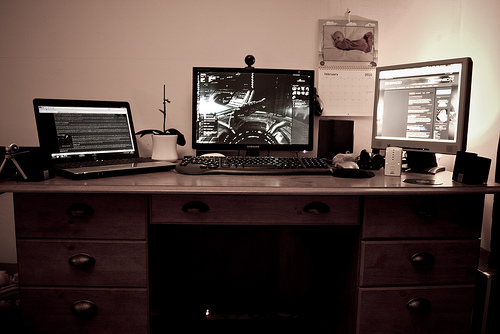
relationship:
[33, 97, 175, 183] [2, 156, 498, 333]
laptop on desk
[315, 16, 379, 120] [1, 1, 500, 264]
calendar hanging on wall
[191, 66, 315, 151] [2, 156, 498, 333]
monitor on desk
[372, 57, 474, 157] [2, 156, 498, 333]
monitor on desk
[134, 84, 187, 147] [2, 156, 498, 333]
plant on desk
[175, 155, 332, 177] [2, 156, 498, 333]
keyboard on desk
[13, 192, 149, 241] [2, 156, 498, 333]
drawer in desk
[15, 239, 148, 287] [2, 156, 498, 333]
drawer in desk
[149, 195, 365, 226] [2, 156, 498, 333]
drawer in desk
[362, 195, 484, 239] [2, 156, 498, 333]
drawer in desk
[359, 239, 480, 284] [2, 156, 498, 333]
drawer in desk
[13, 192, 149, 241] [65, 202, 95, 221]
drawer has handle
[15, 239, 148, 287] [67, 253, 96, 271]
drawer has handle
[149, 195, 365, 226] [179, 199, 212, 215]
drawer has handle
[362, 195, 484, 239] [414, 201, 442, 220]
drawer has handle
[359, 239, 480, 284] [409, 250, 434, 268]
drawer has handle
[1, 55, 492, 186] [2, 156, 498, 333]
objects are on desk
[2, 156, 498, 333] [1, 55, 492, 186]
desk under objects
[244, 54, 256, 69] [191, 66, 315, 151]
webcam on monitor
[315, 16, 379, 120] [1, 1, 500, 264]
calendar on wall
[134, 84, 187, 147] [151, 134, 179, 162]
plant in pot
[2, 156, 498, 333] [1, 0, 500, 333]
desk in office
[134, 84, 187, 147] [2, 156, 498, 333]
plant sitting on desk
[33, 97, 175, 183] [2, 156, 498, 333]
laptop sitting on desk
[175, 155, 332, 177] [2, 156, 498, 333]
keyboard sitting on desk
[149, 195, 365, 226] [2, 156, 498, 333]
drawer on desk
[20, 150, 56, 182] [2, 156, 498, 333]
speaker on desk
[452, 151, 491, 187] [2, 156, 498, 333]
speaker on desk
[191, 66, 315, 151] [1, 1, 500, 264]
monitor against wall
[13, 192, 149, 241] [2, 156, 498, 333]
drawer in front of desk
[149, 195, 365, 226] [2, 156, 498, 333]
drawer in front of desk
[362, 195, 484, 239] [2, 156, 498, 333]
drawer in front of desk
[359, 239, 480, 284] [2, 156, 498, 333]
drawer in front of desk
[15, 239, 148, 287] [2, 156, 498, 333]
drawer in front of desk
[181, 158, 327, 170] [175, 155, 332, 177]
buttons are on keyboard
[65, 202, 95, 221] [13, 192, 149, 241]
handle on drawer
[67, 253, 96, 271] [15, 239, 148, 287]
handle on drawer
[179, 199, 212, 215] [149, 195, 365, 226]
handle on drawer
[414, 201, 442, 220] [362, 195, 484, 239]
handle on drawer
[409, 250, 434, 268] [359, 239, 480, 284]
handle on drawer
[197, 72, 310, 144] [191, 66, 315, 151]
image on monitor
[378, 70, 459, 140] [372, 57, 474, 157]
image on monitor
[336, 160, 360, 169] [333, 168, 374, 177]
computer mouse on pad